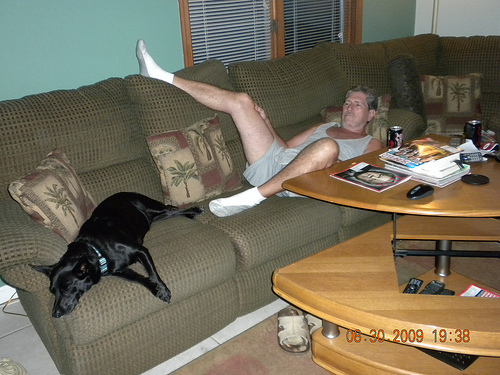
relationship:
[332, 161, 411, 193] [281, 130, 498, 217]
magazine on table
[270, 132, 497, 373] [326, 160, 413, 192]
table with magazine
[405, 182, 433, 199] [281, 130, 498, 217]
mouse on table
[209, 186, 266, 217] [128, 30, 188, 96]
sock on foot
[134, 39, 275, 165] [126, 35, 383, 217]
foot of man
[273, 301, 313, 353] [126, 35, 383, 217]
shoe of man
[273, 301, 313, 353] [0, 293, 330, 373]
shoe on floor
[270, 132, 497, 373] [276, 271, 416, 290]
table made of wood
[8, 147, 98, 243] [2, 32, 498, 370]
pillow on couch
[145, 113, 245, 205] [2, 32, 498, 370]
pillow on couch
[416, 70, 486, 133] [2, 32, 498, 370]
pillow on couch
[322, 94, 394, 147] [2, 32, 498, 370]
pillow on couch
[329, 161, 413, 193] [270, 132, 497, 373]
magazine on table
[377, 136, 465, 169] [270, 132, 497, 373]
magazine on table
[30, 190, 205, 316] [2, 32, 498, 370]
dog sleeping on couch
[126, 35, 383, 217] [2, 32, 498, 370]
man laying on couch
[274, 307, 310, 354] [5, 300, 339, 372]
shoe on floor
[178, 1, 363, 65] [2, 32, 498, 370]
window behind couch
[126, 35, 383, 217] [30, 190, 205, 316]
man with dog